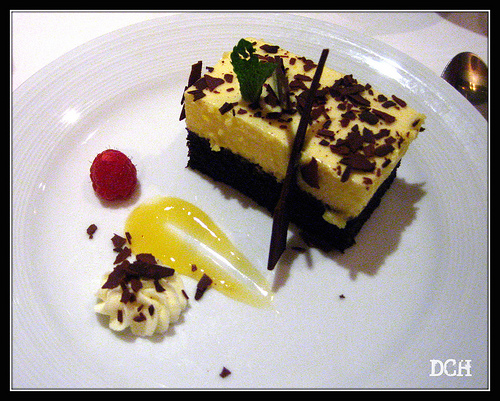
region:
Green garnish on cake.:
[229, 40, 272, 103]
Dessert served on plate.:
[85, 31, 427, 351]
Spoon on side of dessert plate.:
[443, 42, 488, 114]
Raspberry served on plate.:
[85, 140, 145, 201]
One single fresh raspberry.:
[77, 136, 137, 206]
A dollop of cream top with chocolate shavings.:
[90, 250, 190, 330]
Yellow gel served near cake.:
[120, 195, 270, 310]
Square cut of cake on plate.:
[180, 30, 415, 262]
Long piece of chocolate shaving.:
[252, 33, 330, 271]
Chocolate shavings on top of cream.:
[95, 252, 180, 297]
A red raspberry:
[90, 141, 136, 201]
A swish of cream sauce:
[122, 203, 237, 257]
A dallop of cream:
[92, 263, 187, 333]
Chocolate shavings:
[106, 259, 166, 284]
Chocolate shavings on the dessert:
[342, 123, 381, 166]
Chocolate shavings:
[336, 68, 370, 103]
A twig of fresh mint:
[232, 42, 270, 100]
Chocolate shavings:
[176, 65, 227, 91]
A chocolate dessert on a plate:
[176, 20, 429, 241]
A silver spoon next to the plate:
[438, 35, 486, 112]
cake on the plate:
[181, 42, 414, 245]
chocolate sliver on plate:
[196, 275, 213, 302]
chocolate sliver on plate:
[113, 234, 135, 256]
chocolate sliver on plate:
[216, 362, 243, 383]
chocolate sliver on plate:
[303, 153, 323, 185]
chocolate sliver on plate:
[374, 110, 395, 121]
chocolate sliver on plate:
[341, 155, 375, 171]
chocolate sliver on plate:
[219, 101, 236, 115]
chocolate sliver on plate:
[203, 72, 221, 89]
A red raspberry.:
[86, 148, 140, 202]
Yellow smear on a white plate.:
[123, 198, 273, 307]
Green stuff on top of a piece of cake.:
[231, 39, 274, 104]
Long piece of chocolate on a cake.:
[266, 45, 332, 268]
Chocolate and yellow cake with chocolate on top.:
[184, 35, 427, 252]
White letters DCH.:
[429, 358, 471, 377]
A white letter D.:
[429, 357, 444, 376]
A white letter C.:
[442, 358, 458, 375]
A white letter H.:
[455, 355, 470, 377]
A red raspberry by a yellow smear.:
[87, 148, 140, 200]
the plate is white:
[392, 283, 471, 341]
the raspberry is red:
[83, 140, 143, 209]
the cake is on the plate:
[175, 33, 418, 196]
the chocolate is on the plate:
[82, 244, 173, 287]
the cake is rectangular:
[165, 27, 420, 249]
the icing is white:
[103, 277, 174, 330]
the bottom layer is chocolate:
[181, 140, 250, 200]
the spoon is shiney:
[452, 53, 487, 85]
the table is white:
[12, 18, 69, 46]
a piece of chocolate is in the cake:
[257, 41, 342, 270]